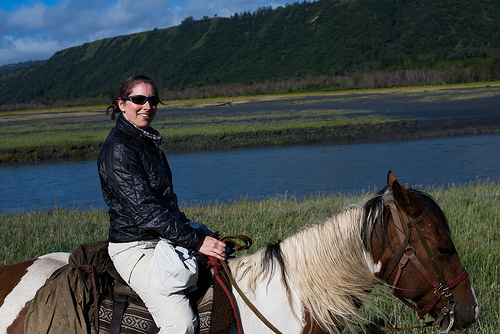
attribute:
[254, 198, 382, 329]
horse's mane — white, black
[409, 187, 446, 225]
hair — black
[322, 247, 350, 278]
hair — white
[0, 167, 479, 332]
horse — brown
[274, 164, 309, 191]
water — blue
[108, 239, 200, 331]
pants — white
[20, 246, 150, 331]
blanket — brown